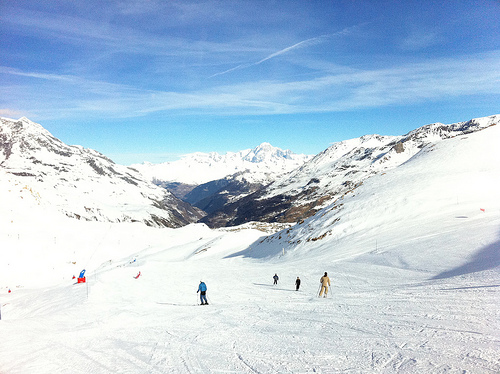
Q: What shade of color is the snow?
A: White.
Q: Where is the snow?
A: On the ground.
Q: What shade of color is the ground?
A: White.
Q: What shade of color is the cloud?
A: White.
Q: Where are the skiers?
A: On the slope.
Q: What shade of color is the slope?
A: White.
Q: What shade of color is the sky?
A: Blue.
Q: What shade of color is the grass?
A: Green.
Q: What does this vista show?
A: Skiers, on a flat, snowy area, with lots of trails, between tall, snow-capped mountains.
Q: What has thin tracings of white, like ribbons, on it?
A: The deep, blue sky.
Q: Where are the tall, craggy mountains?
A: To the rear of the view, bordering three sides of the skiing area.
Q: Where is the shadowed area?
A: In the valley, between the ring of mountains, in the rear of the picture.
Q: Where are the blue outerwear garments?
A: On two of the people, visible in the skiing area.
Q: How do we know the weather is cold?
A: We know, because the terrain is snowy and the people have heavy clothing on.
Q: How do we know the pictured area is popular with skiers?
A: We know, because there are many, many trails criss-crossing the snow, indicating it is used alot.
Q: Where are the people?
A: On the snow.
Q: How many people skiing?
A: Four.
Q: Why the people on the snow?
A: To ski.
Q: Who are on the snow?
A: People.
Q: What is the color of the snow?
A: White.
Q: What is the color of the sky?
A: Blue.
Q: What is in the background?
A: Mountains.